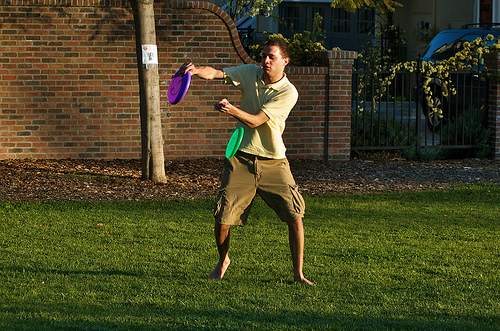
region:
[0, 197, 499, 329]
Lush, green grass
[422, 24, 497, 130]
parked, black car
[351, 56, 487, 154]
small, black,metal gate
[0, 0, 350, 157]
brick wall next to gate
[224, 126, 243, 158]
small, green frisbee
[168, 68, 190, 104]
big, purple frisbee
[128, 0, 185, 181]
large, brown trunk of tree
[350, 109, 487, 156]
green shrubs by the gate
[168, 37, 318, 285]
guy playing with two frisbees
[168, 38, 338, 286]
guy outside, barefoot on grass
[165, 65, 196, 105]
Frisbee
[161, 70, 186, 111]
purple Frisbee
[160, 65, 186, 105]
purple Frisbee held by young man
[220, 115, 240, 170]
green Frisbee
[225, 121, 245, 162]
green Frisbee dropped by young man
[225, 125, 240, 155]
Frisbee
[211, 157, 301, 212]
tan pants worn by young man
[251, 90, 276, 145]
tan shirt worn by young man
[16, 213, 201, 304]
short green grass in park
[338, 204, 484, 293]
short green grass in park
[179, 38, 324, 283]
a man playing with a frisbee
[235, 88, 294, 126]
the arm of a man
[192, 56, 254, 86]
the arm of a man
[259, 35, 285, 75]
the head of a man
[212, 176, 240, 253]
the leg the arm of a man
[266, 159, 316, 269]
the leg of a man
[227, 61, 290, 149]
a pale yellow t-shirt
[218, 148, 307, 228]
a pair of khaki cargo shorts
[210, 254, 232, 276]
the foot of a man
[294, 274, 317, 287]
the foot of a man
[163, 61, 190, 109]
Frisbee held by young man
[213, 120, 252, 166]
Frisbee held by young man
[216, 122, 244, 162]
green Frisbee held by young man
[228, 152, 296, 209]
tan shorts worn by young man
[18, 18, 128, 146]
red gray and brown brick wall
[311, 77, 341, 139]
red gray and brown brick wall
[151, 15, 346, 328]
a man with two frisbees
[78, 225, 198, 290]
sunlight shining on the grass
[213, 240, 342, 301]
a man's bare feet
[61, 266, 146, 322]
the shadow of trees on the grass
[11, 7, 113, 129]
multiple colored bricks on a wall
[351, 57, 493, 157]
a black metal fence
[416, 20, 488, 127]
the side of a black vehicle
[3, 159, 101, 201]
brown leaves on the ground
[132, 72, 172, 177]
a gray tree trunk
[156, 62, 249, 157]
one green and one purple frisbee